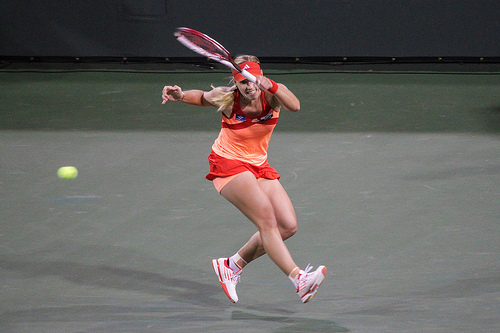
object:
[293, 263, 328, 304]
shoe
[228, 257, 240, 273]
socks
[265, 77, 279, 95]
band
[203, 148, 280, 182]
skirt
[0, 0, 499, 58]
tarp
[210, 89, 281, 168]
shirt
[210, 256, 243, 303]
shoe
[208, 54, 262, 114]
hair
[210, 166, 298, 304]
leg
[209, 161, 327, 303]
leg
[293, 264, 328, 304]
feet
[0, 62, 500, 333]
ground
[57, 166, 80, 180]
tennis ball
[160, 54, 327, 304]
player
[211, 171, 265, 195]
shorts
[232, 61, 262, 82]
hat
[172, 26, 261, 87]
racket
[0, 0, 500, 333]
game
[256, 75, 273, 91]
hand